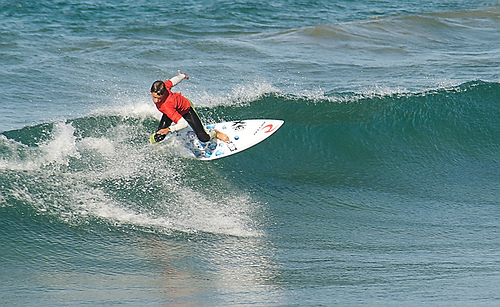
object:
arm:
[158, 106, 189, 134]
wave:
[0, 0, 499, 242]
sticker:
[230, 120, 249, 131]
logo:
[254, 121, 279, 136]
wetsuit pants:
[148, 98, 218, 145]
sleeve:
[163, 73, 187, 89]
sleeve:
[158, 103, 190, 134]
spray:
[0, 67, 499, 242]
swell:
[0, 76, 500, 244]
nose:
[152, 98, 162, 106]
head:
[148, 79, 167, 104]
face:
[150, 89, 165, 106]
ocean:
[0, 0, 499, 307]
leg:
[182, 107, 217, 143]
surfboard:
[176, 117, 286, 162]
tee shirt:
[153, 72, 192, 134]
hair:
[148, 78, 168, 97]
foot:
[212, 128, 231, 142]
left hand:
[156, 127, 170, 136]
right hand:
[177, 69, 190, 80]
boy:
[146, 68, 231, 147]